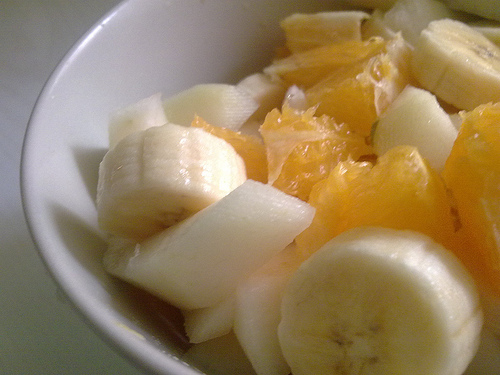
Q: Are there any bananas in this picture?
A: Yes, there is a banana.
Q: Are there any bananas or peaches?
A: Yes, there is a banana.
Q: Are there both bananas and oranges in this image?
A: Yes, there are both a banana and oranges.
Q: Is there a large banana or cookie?
A: Yes, there is a large banana.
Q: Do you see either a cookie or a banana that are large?
A: Yes, the banana is large.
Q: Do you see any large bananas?
A: Yes, there is a large banana.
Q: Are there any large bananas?
A: Yes, there is a large banana.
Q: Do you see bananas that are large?
A: Yes, there is a banana that is large.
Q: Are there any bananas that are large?
A: Yes, there is a banana that is large.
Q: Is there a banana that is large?
A: Yes, there is a banana that is large.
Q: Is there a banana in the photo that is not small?
A: Yes, there is a large banana.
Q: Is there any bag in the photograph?
A: No, there are no bags.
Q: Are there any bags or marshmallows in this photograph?
A: No, there are no bags or marshmallows.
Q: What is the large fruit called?
A: The fruit is a banana.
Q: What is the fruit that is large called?
A: The fruit is a banana.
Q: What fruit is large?
A: The fruit is a banana.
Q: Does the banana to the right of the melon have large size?
A: Yes, the banana is large.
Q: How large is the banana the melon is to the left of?
A: The banana is large.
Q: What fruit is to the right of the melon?
A: The fruit is a banana.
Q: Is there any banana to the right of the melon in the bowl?
A: Yes, there is a banana to the right of the melon.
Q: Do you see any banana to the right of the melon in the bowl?
A: Yes, there is a banana to the right of the melon.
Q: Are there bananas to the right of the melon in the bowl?
A: Yes, there is a banana to the right of the melon.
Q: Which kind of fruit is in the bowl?
A: The fruit is a banana.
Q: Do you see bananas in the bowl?
A: Yes, there is a banana in the bowl.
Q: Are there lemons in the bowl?
A: No, there is a banana in the bowl.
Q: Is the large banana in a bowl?
A: Yes, the banana is in a bowl.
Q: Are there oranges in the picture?
A: Yes, there are oranges.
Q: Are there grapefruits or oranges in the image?
A: Yes, there are oranges.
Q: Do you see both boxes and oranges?
A: No, there are oranges but no boxes.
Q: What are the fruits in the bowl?
A: The fruits are oranges.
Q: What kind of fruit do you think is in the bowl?
A: The fruits are oranges.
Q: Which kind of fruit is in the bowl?
A: The fruits are oranges.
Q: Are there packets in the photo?
A: No, there are no packets.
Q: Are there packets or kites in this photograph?
A: No, there are no packets or kites.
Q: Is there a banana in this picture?
A: Yes, there is a banana.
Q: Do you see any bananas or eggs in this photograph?
A: Yes, there is a banana.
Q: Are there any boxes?
A: No, there are no boxes.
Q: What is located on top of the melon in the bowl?
A: The banana is on top of the melon.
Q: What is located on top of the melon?
A: The banana is on top of the melon.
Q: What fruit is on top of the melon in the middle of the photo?
A: The fruit is a banana.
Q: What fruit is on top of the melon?
A: The fruit is a banana.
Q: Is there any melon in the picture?
A: Yes, there is a melon.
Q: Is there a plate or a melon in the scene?
A: Yes, there is a melon.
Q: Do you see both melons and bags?
A: No, there is a melon but no bags.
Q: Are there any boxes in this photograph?
A: No, there are no boxes.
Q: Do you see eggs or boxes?
A: No, there are no boxes or eggs.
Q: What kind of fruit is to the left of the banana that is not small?
A: The fruit is a melon.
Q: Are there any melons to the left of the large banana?
A: Yes, there is a melon to the left of the banana.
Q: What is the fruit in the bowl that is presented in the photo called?
A: The fruit is a melon.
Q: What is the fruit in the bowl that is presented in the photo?
A: The fruit is a melon.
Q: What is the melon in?
A: The melon is in the bowl.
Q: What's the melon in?
A: The melon is in the bowl.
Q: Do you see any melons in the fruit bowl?
A: Yes, there is a melon in the bowl.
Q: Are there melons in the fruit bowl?
A: Yes, there is a melon in the bowl.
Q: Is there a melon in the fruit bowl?
A: Yes, there is a melon in the bowl.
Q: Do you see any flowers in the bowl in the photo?
A: No, there is a melon in the bowl.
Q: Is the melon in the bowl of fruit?
A: Yes, the melon is in the bowl.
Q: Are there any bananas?
A: Yes, there are bananas.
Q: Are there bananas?
A: Yes, there are bananas.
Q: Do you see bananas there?
A: Yes, there are bananas.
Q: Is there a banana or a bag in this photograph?
A: Yes, there are bananas.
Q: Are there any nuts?
A: No, there are no nuts.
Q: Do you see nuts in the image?
A: No, there are no nuts.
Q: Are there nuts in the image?
A: No, there are no nuts.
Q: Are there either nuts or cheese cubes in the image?
A: No, there are no nuts or cheese cubes.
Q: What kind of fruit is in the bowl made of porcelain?
A: The fruits are bananas.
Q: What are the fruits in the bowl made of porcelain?
A: The fruits are bananas.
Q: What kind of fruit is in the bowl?
A: The fruits are bananas.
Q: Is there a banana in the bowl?
A: Yes, there are bananas in the bowl.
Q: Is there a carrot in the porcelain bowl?
A: No, there are bananas in the bowl.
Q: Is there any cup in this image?
A: No, there are no cups.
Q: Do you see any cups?
A: No, there are no cups.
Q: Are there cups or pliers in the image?
A: No, there are no cups or pliers.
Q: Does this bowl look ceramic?
A: Yes, the bowl is ceramic.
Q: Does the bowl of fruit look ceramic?
A: Yes, the bowl is ceramic.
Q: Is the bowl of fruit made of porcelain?
A: Yes, the bowl is made of porcelain.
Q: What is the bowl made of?
A: The bowl is made of porcelain.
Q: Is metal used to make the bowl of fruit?
A: No, the bowl is made of porcelain.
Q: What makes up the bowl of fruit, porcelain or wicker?
A: The bowl is made of porcelain.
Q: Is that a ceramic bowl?
A: Yes, that is a ceramic bowl.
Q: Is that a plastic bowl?
A: No, that is a ceramic bowl.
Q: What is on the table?
A: The bowl is on the table.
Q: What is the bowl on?
A: The bowl is on the table.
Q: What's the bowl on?
A: The bowl is on the table.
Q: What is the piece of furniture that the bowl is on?
A: The piece of furniture is a table.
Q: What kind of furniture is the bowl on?
A: The bowl is on the table.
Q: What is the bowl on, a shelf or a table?
A: The bowl is on a table.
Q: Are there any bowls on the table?
A: Yes, there is a bowl on the table.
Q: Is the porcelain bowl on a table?
A: Yes, the bowl is on a table.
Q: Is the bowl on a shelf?
A: No, the bowl is on a table.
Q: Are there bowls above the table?
A: Yes, there is a bowl above the table.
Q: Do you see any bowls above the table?
A: Yes, there is a bowl above the table.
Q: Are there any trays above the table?
A: No, there is a bowl above the table.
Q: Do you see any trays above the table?
A: No, there is a bowl above the table.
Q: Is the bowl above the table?
A: Yes, the bowl is above the table.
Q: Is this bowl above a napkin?
A: No, the bowl is above the table.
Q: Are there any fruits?
A: Yes, there is a fruit.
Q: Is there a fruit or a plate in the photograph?
A: Yes, there is a fruit.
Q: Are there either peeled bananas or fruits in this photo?
A: Yes, there is a peeled fruit.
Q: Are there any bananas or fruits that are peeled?
A: Yes, the fruit is peeled.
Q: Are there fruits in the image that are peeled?
A: Yes, there is a peeled fruit.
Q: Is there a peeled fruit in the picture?
A: Yes, there is a peeled fruit.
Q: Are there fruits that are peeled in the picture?
A: Yes, there is a peeled fruit.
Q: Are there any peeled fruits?
A: Yes, there is a peeled fruit.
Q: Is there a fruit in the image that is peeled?
A: Yes, there is a fruit that is peeled.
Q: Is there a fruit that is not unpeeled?
A: Yes, there is an peeled fruit.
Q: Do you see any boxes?
A: No, there are no boxes.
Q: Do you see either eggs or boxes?
A: No, there are no boxes or eggs.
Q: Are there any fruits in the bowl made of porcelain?
A: Yes, there is a fruit in the bowl.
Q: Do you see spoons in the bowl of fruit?
A: No, there is a fruit in the bowl.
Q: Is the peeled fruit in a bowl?
A: Yes, the fruit is in a bowl.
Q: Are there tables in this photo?
A: Yes, there is a table.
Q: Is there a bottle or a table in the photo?
A: Yes, there is a table.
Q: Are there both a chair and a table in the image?
A: No, there is a table but no chairs.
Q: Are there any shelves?
A: No, there are no shelves.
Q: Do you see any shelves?
A: No, there are no shelves.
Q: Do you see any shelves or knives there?
A: No, there are no shelves or knives.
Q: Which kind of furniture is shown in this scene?
A: The furniture is a table.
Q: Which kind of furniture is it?
A: The piece of furniture is a table.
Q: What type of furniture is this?
A: This is a table.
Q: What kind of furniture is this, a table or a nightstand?
A: This is a table.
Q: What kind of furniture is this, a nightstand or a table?
A: This is a table.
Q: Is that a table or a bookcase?
A: That is a table.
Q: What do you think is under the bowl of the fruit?
A: The table is under the bowl.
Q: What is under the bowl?
A: The table is under the bowl.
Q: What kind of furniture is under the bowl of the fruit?
A: The piece of furniture is a table.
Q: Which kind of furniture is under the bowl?
A: The piece of furniture is a table.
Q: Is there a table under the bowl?
A: Yes, there is a table under the bowl.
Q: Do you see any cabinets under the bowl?
A: No, there is a table under the bowl.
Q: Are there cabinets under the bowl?
A: No, there is a table under the bowl.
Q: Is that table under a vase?
A: No, the table is under the bowl.